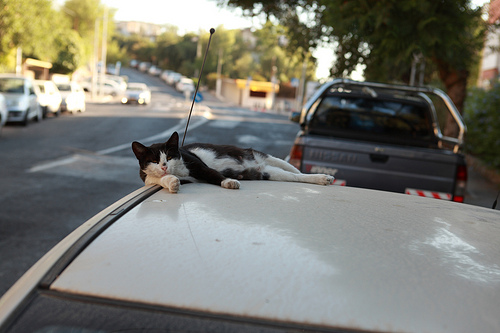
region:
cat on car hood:
[125, 138, 338, 206]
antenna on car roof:
[176, 24, 218, 147]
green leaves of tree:
[345, 8, 435, 56]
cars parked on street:
[10, 73, 96, 119]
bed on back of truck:
[317, 135, 464, 185]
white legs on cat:
[275, 153, 335, 195]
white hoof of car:
[219, 211, 337, 282]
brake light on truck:
[440, 156, 477, 203]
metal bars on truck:
[432, 87, 466, 150]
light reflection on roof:
[436, 223, 485, 280]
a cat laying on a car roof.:
[134, 108, 349, 206]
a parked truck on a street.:
[290, 48, 477, 200]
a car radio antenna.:
[170, 21, 237, 148]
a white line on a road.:
[23, 86, 230, 184]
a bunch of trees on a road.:
[0, 0, 125, 107]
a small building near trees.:
[227, 33, 278, 124]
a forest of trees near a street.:
[120, 11, 319, 119]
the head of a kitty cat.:
[118, 111, 208, 198]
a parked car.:
[118, 78, 160, 120]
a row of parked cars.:
[127, 51, 195, 100]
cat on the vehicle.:
[150, 150, 247, 177]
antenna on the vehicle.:
[181, 25, 220, 120]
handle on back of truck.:
[365, 152, 390, 164]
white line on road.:
[193, 109, 211, 128]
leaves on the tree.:
[38, 27, 61, 46]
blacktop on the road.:
[65, 119, 122, 141]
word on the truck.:
[307, 152, 354, 160]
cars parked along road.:
[166, 72, 188, 91]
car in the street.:
[116, 82, 151, 114]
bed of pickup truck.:
[320, 124, 433, 138]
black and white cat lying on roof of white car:
[1, 127, 498, 330]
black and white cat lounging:
[129, 130, 334, 192]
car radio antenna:
[180, 25, 217, 150]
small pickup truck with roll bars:
[288, 77, 468, 204]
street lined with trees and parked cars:
[1, 0, 496, 285]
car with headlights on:
[121, 80, 152, 104]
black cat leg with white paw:
[183, 152, 240, 188]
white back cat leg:
[266, 166, 336, 184]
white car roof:
[52, 177, 499, 331]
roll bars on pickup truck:
[297, 79, 466, 149]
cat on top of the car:
[125, 99, 382, 242]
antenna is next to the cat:
[169, 10, 242, 212]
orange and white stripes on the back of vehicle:
[301, 166, 481, 208]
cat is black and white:
[126, 113, 380, 232]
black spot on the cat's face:
[141, 146, 185, 181]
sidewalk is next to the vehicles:
[449, 115, 498, 197]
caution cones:
[238, 98, 269, 118]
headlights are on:
[110, 80, 154, 110]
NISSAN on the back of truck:
[305, 139, 433, 198]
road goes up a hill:
[99, 22, 189, 95]